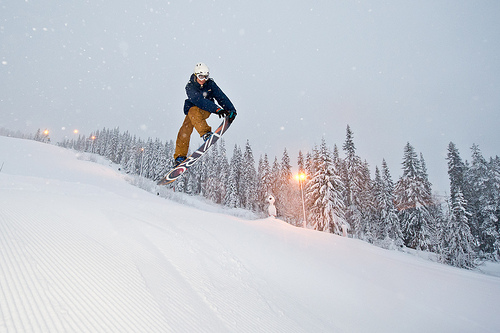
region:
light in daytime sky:
[11, 2, 495, 129]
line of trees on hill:
[3, 126, 497, 264]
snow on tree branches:
[308, 146, 352, 231]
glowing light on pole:
[291, 169, 308, 224]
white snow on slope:
[1, 135, 498, 331]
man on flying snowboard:
[157, 62, 234, 188]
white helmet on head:
[193, 61, 208, 83]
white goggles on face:
[195, 72, 207, 85]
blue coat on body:
[183, 80, 230, 114]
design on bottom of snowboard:
[163, 119, 230, 184]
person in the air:
[121, 32, 266, 197]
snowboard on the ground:
[145, 111, 241, 201]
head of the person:
[180, 65, 215, 90]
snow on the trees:
[305, 155, 370, 225]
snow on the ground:
[135, 255, 235, 320]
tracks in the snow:
[100, 280, 175, 325]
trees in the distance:
[35, 120, 100, 160]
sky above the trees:
[340, 10, 430, 70]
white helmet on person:
[181, 50, 226, 90]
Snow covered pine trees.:
[387, 124, 486, 246]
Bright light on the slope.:
[285, 166, 312, 234]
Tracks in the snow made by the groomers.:
[16, 184, 89, 323]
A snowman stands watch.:
[257, 189, 283, 223]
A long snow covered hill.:
[15, 148, 62, 330]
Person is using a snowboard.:
[155, 51, 242, 193]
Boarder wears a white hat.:
[186, 57, 216, 79]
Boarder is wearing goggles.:
[187, 68, 212, 83]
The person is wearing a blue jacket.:
[173, 79, 231, 110]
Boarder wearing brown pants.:
[166, 100, 213, 161]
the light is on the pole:
[292, 159, 327, 233]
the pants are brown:
[169, 104, 209, 154]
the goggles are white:
[194, 68, 214, 82]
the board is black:
[152, 111, 242, 187]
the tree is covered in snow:
[303, 123, 357, 247]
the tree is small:
[436, 184, 487, 280]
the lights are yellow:
[281, 163, 318, 188]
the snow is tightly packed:
[47, 235, 171, 313]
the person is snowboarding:
[164, 30, 247, 190]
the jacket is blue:
[176, 82, 224, 120]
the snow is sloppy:
[0, 141, 499, 329]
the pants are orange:
[165, 100, 243, 152]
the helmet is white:
[191, 55, 216, 87]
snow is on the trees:
[232, 145, 473, 233]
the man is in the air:
[148, 68, 276, 203]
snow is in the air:
[42, 23, 218, 80]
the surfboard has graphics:
[173, 125, 237, 176]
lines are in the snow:
[16, 244, 117, 330]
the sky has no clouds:
[65, 24, 499, 58]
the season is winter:
[9, 20, 484, 330]